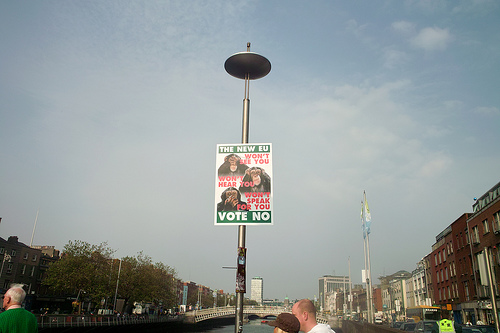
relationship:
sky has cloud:
[1, 0, 500, 301] [406, 27, 451, 53]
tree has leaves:
[39, 240, 115, 318] [40, 241, 113, 302]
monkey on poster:
[240, 168, 270, 195] [214, 142, 273, 227]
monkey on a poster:
[217, 154, 249, 180] [214, 142, 273, 227]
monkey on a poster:
[218, 188, 249, 212] [214, 142, 273, 227]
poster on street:
[214, 142, 273, 227] [373, 317, 396, 329]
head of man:
[4, 285, 25, 307] [0, 285, 41, 333]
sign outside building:
[394, 299, 401, 313] [389, 275, 406, 325]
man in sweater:
[0, 285, 41, 333] [0, 307, 39, 332]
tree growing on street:
[39, 240, 115, 318] [33, 310, 184, 327]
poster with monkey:
[214, 142, 273, 227] [240, 168, 270, 195]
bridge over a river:
[184, 306, 235, 324] [198, 322, 235, 333]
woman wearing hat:
[277, 313, 300, 333] [275, 313, 299, 333]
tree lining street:
[39, 240, 115, 318] [33, 310, 184, 327]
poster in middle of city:
[214, 142, 273, 227] [2, 3, 497, 332]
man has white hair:
[0, 285, 41, 333] [8, 287, 25, 304]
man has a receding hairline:
[292, 298, 337, 332] [294, 301, 301, 307]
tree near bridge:
[112, 252, 158, 317] [184, 306, 235, 324]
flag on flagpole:
[364, 190, 370, 223] [368, 190, 374, 325]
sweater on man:
[0, 307, 39, 332] [0, 285, 41, 333]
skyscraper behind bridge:
[250, 277, 262, 303] [184, 306, 235, 324]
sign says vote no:
[214, 142, 273, 227] [215, 210, 271, 226]